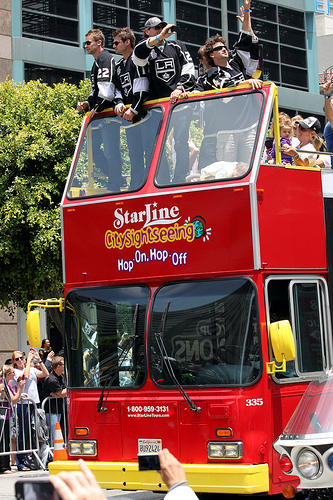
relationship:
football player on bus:
[137, 14, 197, 99] [66, 87, 312, 410]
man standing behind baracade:
[5, 345, 48, 467] [0, 393, 70, 453]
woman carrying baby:
[282, 116, 320, 168] [270, 112, 295, 165]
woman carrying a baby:
[281, 116, 320, 164] [267, 119, 292, 162]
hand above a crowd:
[101, 24, 213, 48] [0, 441, 201, 496]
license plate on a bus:
[133, 436, 162, 458] [47, 81, 332, 500]